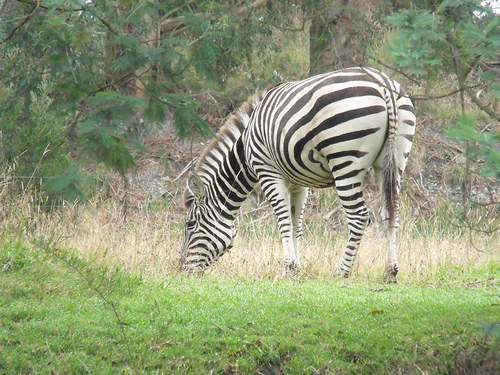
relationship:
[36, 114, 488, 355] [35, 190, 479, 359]
grass on ground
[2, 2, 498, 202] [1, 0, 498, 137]
green leaves on branches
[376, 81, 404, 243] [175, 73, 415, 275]
tail of zebra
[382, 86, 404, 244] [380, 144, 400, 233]
tail with fur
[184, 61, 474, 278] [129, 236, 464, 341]
zebra eating grass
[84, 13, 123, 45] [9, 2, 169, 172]
branches have leaves